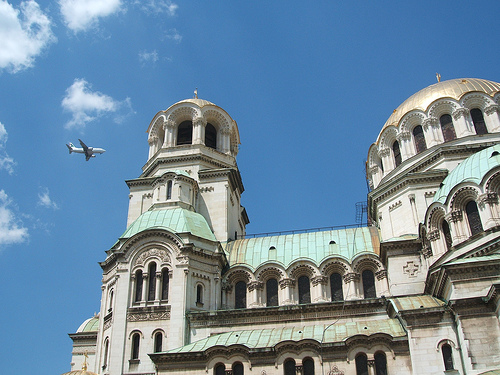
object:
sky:
[0, 0, 500, 86]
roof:
[228, 226, 380, 272]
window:
[285, 263, 320, 305]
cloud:
[53, 0, 126, 35]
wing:
[78, 138, 89, 151]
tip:
[435, 70, 441, 83]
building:
[67, 69, 499, 375]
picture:
[0, 0, 500, 375]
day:
[0, 0, 500, 93]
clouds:
[54, 78, 137, 134]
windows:
[352, 253, 385, 299]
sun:
[0, 0, 141, 85]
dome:
[374, 76, 499, 142]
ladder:
[193, 184, 200, 212]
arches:
[166, 106, 199, 147]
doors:
[204, 122, 218, 149]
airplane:
[65, 137, 107, 162]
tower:
[124, 86, 251, 253]